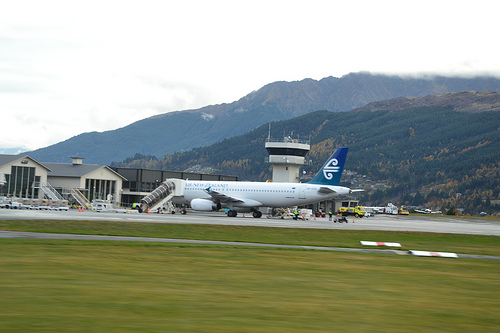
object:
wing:
[205, 187, 240, 210]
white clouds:
[82, 23, 139, 36]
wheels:
[226, 208, 238, 217]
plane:
[141, 146, 364, 218]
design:
[323, 157, 340, 178]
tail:
[308, 145, 348, 182]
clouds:
[2, 40, 25, 59]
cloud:
[22, 97, 37, 110]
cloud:
[74, 79, 110, 117]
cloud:
[145, 53, 192, 92]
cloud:
[240, 28, 291, 48]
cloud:
[313, 18, 381, 55]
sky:
[410, 0, 498, 59]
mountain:
[111, 91, 498, 216]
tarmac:
[2, 210, 499, 234]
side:
[177, 180, 320, 205]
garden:
[421, 275, 444, 299]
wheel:
[252, 211, 262, 219]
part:
[253, 213, 257, 217]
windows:
[189, 183, 296, 192]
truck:
[337, 199, 367, 218]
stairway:
[134, 179, 177, 216]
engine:
[190, 197, 222, 211]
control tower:
[264, 122, 311, 182]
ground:
[131, 290, 270, 330]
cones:
[43, 177, 405, 217]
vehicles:
[2, 190, 109, 213]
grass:
[32, 312, 59, 331]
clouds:
[176, 46, 206, 59]